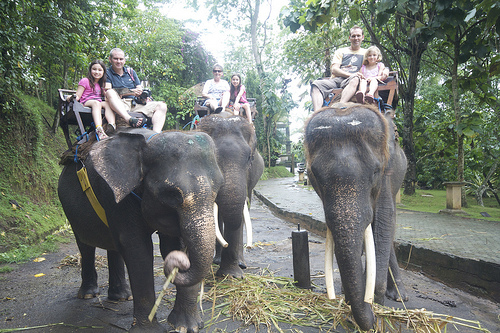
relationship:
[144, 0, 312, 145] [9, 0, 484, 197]
sky between trees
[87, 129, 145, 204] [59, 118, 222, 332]
ear of elephant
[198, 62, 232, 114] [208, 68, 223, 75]
people wearing goggles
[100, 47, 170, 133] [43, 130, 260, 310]
man on elephant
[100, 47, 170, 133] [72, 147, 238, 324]
man on elephant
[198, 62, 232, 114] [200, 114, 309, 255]
people on elephant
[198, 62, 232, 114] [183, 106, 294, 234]
people on elephant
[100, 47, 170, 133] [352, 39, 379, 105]
man with daughter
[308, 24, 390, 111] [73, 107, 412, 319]
man on elephants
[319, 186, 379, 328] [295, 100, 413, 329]
trunk of elephant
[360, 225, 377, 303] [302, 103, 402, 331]
tusk of elephant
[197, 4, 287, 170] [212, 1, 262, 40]
tree with leaves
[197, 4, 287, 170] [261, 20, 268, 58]
tree with branches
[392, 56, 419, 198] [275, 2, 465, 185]
trunk of tree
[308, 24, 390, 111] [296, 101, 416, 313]
man riding elephant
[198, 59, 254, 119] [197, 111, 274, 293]
people riding elephant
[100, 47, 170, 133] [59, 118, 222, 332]
man riding elephant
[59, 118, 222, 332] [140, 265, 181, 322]
elephant grasping stick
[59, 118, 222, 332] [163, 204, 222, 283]
elephant grasping with trunk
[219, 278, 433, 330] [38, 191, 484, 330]
straw scattered on path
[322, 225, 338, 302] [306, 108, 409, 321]
tusk of elephant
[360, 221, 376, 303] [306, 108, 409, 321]
tusk of elephant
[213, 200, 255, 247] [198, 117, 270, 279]
tusks of elephant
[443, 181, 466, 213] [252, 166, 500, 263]
garbage can along roadside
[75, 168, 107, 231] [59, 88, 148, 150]
strap holding seat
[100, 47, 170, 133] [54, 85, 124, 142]
man sitting on seat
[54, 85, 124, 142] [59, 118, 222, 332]
seat on back of elephant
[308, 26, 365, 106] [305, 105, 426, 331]
man sitting on elephant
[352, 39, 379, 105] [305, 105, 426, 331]
daughter sitting on elephant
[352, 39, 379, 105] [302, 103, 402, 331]
daughter on elephant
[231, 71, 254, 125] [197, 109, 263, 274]
girl on elephant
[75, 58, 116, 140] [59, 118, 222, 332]
girl on elephant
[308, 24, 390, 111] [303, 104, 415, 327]
man seated on elephant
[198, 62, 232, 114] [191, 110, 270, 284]
people on elephant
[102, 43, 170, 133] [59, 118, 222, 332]
man on elephant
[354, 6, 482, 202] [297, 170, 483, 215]
tree on roadside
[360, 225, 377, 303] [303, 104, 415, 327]
tusk on elephant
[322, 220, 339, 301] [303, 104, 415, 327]
tusk on elephant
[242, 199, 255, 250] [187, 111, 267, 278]
tusk on elephant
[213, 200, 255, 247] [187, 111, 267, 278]
tusks on elephant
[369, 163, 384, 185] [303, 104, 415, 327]
eye on elephant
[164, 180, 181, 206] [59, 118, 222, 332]
eye on elephant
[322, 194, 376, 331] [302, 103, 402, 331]
trunk on elephant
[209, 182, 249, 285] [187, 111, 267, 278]
trunk on elephant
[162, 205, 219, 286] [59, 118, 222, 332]
trunk on elephant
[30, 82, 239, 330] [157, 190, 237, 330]
elephant has a trunk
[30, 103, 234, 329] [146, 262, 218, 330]
elephant has a foot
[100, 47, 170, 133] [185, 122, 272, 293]
man on elephant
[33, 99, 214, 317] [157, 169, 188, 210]
elephant has an eye